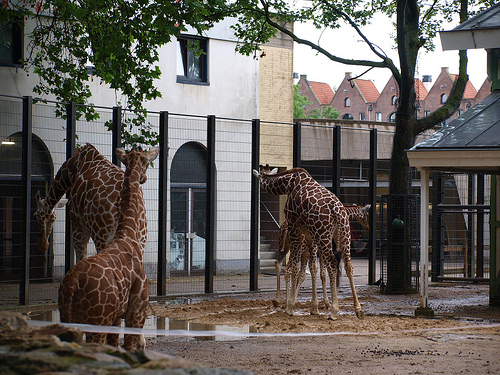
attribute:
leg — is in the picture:
[109, 315, 126, 355]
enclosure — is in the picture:
[433, 172, 490, 283]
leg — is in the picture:
[307, 244, 321, 316]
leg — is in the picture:
[128, 285, 149, 355]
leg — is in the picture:
[316, 234, 343, 323]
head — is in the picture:
[116, 140, 158, 185]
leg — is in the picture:
[309, 254, 321, 319]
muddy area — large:
[137, 297, 447, 338]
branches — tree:
[35, 0, 162, 167]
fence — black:
[5, 89, 490, 294]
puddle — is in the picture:
[74, 297, 366, 348]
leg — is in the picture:
[325, 266, 342, 326]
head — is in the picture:
[252, 163, 279, 192]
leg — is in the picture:
[326, 259, 366, 325]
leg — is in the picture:
[289, 266, 304, 306]